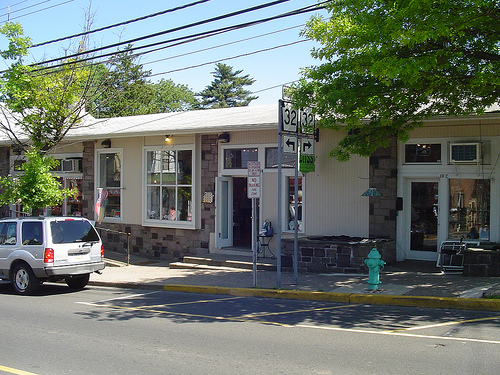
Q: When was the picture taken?
A: Daytime.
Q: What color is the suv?
A: White.